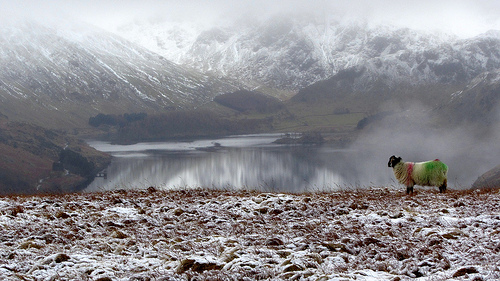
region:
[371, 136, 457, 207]
animal colored tan, pink, white and green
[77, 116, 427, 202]
lake on bottom of valley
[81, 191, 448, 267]
frost covering brown ground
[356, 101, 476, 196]
mist rising on side of lake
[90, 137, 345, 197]
reflection on lake water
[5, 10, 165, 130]
mountain covered in lines of snow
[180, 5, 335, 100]
ridges partially covered in snow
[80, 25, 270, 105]
smooth slope of mountian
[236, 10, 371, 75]
rough terrain across mountain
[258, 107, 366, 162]
land jutting out into lake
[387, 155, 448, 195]
a multi colored sheep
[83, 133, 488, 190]
a lake at the foot of the mountains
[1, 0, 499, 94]
snow caped mountain range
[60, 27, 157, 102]
a trail formed from water runoff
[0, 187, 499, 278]
snow powdered grazing grass area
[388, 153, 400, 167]
the head of the sheep is black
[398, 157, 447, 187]
the sheep's wool is red and green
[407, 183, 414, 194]
"the sheep's legs are black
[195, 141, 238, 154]
there's an Island in the middle of the lake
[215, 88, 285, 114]
a plat of tall vegetation on the other side of the lake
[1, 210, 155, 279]
Snow covered brown rocks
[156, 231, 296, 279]
Snow covered brown rocks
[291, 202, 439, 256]
Snow covered brown rocks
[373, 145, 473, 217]
Red, white and green painted sheep on snow covered ground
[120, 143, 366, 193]
Calm, reflection on lake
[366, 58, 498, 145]
Gray mist over lake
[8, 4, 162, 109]
Snow covered brown mountains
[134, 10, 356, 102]
Snow covered brown mountains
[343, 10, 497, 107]
Snow covered brown mountains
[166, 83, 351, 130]
Distant green and brown hills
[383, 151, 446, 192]
Sheep standing on a hill.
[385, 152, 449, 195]
Sheep with red, white, and green wool.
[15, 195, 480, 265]
Snow on the grass.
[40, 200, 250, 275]
Brown grass and white snow.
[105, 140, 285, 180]
Small river below the hill.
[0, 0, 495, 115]
Snow on the mountains.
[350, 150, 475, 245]
Sheep standing on snowy grass.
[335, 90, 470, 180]
Fog above the small river.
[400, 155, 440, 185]
Green, white and red wool.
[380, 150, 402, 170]
Sheep with black head.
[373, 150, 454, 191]
Sheep with green red and yellow paint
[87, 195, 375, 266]
Ice covered dried grass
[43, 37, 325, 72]
Snow capped mountains in distance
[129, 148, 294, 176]
Cold partially frozen lake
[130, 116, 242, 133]
Winter trees in background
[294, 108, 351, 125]
Green grass in winter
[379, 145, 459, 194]
Lonely multi-colored sheep.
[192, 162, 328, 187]
Reflection of snow capped mountains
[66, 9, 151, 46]
Low clouds partially covering mountain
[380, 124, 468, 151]
Low fog partially covering lake